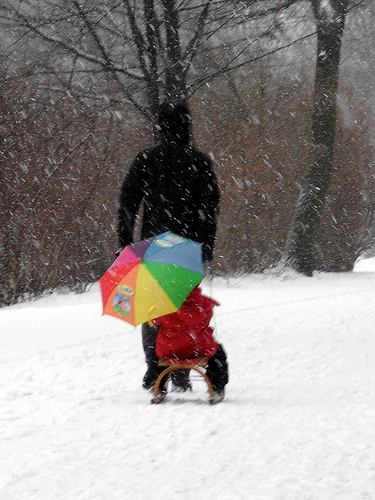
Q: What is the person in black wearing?
A: Jacket.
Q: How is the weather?
A: Snowy.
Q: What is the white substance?
A: Snow.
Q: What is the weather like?
A: Snowing.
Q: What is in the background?
A: Snow.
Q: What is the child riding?
A: Sled.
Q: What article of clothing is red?
A: Jacket.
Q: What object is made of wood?
A: Sled.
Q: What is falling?
A: Snow.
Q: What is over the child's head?
A: Umbrella.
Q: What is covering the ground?
A: Snow.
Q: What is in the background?
A: Trees.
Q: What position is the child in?
A: Sitting.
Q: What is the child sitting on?
A: Sled.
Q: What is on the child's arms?
A: Coat.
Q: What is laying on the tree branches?
A: Snow.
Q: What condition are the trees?
A: Bare.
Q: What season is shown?
A: Winter.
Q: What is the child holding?
A: Umbrella.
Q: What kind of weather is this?
A: Snowing.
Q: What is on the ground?
A: Snow.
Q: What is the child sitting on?
A: Sled.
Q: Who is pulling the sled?
A: Person in black coat with black hood.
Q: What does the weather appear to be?
A: Snowy,.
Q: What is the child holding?
A: Umbrella.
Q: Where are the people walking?
A: To woods.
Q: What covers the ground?
A: Snow.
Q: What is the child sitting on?
A: Sled.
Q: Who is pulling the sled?
A: A man,.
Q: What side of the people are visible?
A: Backside.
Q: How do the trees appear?
A: Bare.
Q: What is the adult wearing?
A: Black jacket.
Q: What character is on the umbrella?
A: Dora.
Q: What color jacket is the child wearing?
A: Red.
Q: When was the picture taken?
A: During the day.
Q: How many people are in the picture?
A: Two.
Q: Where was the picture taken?
A: Outside in the snow.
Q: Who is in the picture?
A: A man and a child.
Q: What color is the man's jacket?
A: Black.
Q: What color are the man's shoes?
A: Black.